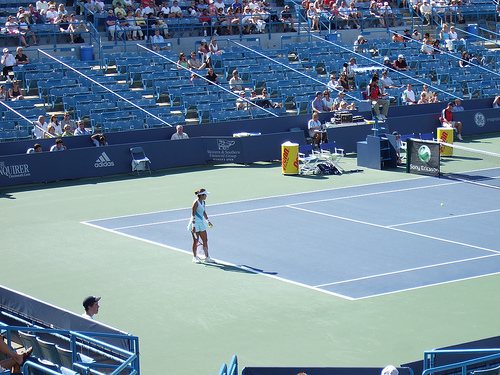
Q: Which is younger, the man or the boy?
A: The boy is younger than the man.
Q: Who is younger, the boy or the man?
A: The boy is younger than the man.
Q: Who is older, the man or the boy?
A: The man is older than the boy.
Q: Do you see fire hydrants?
A: No, there are no fire hydrants.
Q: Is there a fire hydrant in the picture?
A: No, there are no fire hydrants.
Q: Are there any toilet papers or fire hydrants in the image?
A: No, there are no fire hydrants or toilet papers.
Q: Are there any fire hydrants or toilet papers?
A: No, there are no fire hydrants or toilet papers.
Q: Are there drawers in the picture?
A: No, there are no drawers.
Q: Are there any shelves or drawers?
A: No, there are no drawers or shelves.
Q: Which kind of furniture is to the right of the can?
A: The pieces of furniture are chairs.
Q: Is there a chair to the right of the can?
A: Yes, there are chairs to the right of the can.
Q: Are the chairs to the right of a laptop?
A: No, the chairs are to the right of a can.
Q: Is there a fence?
A: No, there are no fences.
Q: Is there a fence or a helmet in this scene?
A: No, there are no fences or helmets.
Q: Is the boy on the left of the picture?
A: Yes, the boy is on the left of the image.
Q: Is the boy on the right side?
A: No, the boy is on the left of the image.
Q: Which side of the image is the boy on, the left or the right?
A: The boy is on the left of the image.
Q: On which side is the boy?
A: The boy is on the left of the image.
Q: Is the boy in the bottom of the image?
A: Yes, the boy is in the bottom of the image.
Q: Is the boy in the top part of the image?
A: No, the boy is in the bottom of the image.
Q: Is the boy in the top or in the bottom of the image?
A: The boy is in the bottom of the image.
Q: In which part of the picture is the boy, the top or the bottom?
A: The boy is in the bottom of the image.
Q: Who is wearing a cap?
A: The boy is wearing a cap.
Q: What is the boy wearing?
A: The boy is wearing a cap.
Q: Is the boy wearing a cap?
A: Yes, the boy is wearing a cap.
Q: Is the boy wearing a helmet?
A: No, the boy is wearing a cap.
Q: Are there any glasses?
A: No, there are no glasses.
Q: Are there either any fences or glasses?
A: No, there are no glasses or fences.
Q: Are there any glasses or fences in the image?
A: No, there are no glasses or fences.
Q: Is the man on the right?
A: Yes, the man is on the right of the image.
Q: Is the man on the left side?
A: No, the man is on the right of the image.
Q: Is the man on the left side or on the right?
A: The man is on the right of the image.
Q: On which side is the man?
A: The man is on the right of the image.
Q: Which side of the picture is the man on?
A: The man is on the right of the image.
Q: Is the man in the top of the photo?
A: Yes, the man is in the top of the image.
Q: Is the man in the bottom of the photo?
A: No, the man is in the top of the image.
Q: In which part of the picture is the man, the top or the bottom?
A: The man is in the top of the image.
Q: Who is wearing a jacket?
A: The man is wearing a jacket.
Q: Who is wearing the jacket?
A: The man is wearing a jacket.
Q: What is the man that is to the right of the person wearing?
A: The man is wearing a jacket.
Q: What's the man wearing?
A: The man is wearing a jacket.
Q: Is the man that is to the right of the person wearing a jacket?
A: Yes, the man is wearing a jacket.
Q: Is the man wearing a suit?
A: No, the man is wearing a jacket.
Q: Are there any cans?
A: Yes, there is a can.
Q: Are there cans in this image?
A: Yes, there is a can.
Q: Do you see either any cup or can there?
A: Yes, there is a can.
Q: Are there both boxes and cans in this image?
A: Yes, there are both a can and a box.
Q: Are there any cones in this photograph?
A: No, there are no cones.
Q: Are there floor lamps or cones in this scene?
A: No, there are no cones or floor lamps.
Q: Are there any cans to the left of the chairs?
A: Yes, there is a can to the left of the chairs.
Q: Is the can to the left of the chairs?
A: Yes, the can is to the left of the chairs.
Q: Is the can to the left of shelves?
A: No, the can is to the left of the chairs.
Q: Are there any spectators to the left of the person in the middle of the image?
A: Yes, there are spectators to the left of the person.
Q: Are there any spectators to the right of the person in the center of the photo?
A: No, the spectators are to the left of the person.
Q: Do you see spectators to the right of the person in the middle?
A: No, the spectators are to the left of the person.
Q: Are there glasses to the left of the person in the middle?
A: No, there are spectators to the left of the person.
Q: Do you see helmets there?
A: No, there are no helmets.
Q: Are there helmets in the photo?
A: No, there are no helmets.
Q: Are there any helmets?
A: No, there are no helmets.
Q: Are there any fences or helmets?
A: No, there are no helmets or fences.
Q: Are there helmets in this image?
A: No, there are no helmets.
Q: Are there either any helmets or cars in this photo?
A: No, there are no helmets or cars.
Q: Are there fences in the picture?
A: No, there are no fences.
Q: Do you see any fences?
A: No, there are no fences.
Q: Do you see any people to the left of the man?
A: Yes, there is a person to the left of the man.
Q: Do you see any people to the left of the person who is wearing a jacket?
A: Yes, there is a person to the left of the man.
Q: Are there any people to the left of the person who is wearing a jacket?
A: Yes, there is a person to the left of the man.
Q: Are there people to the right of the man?
A: No, the person is to the left of the man.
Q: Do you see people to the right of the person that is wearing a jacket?
A: No, the person is to the left of the man.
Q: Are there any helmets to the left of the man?
A: No, there is a person to the left of the man.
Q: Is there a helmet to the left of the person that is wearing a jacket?
A: No, there is a person to the left of the man.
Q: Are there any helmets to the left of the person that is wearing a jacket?
A: No, there is a person to the left of the man.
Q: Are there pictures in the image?
A: No, there are no pictures.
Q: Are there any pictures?
A: No, there are no pictures.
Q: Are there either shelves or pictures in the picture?
A: No, there are no pictures or shelves.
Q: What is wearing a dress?
A: The box is wearing a dress.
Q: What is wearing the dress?
A: The box is wearing a dress.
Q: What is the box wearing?
A: The box is wearing a dress.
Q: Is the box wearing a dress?
A: Yes, the box is wearing a dress.